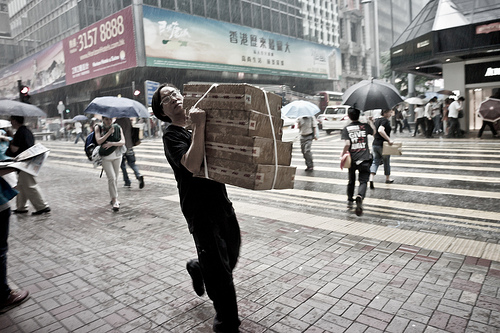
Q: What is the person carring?
A: Boxes.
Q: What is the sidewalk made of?
A: Bricks.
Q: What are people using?
A: Umbrellas.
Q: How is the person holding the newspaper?
A: With their hands.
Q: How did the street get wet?
A: Rain.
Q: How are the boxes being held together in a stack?
A: String.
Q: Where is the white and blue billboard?
A: On the front of the building.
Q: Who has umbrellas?
A: The pedestrians.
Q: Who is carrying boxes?
A: The man.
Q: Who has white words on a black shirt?
A: The man crossing the street.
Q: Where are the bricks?
A: On the sidewalk.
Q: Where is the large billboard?
A: Over the street.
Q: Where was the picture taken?
A: A city.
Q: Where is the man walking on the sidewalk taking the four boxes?
A: To the store.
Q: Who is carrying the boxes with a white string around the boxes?
A: Man on sidewalk.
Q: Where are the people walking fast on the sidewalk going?
A: Shopping.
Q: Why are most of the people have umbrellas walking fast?
A: The weather is raining.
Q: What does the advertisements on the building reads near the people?
A: 3157 8888.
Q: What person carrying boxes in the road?
A: Person wearing glasses.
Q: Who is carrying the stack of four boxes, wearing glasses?
A: Man wearing black pants.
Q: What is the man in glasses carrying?
A: Boxes.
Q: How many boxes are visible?
A: Four.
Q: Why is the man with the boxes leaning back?
A: The boxes are heavy.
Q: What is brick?
A: The walkway.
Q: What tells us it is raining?
A: The umbrellas and the shiny road.